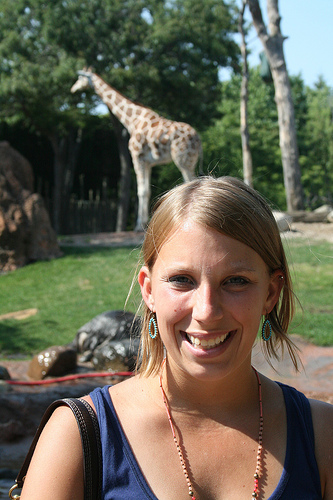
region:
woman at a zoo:
[9, 169, 332, 498]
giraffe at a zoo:
[57, 59, 241, 190]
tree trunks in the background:
[235, 6, 303, 213]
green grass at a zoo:
[24, 268, 134, 304]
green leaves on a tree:
[6, 2, 218, 59]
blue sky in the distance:
[292, 1, 331, 68]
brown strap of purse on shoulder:
[7, 392, 104, 499]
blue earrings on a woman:
[144, 310, 161, 340]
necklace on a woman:
[162, 418, 276, 499]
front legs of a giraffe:
[125, 156, 157, 238]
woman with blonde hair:
[121, 173, 315, 404]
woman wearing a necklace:
[107, 155, 305, 497]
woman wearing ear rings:
[109, 171, 312, 406]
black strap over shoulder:
[5, 384, 122, 499]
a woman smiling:
[124, 197, 312, 394]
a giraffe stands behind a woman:
[57, 52, 217, 250]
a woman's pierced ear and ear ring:
[256, 259, 303, 359]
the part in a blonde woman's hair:
[127, 169, 299, 263]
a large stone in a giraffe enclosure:
[0, 129, 90, 283]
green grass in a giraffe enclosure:
[20, 265, 123, 313]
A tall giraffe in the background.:
[65, 60, 213, 220]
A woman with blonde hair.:
[109, 165, 307, 407]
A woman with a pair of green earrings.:
[131, 166, 317, 377]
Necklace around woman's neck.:
[119, 197, 285, 496]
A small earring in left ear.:
[275, 266, 291, 291]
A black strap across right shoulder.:
[13, 386, 110, 498]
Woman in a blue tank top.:
[83, 164, 328, 498]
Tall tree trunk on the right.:
[264, 59, 308, 213]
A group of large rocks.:
[32, 310, 139, 376]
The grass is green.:
[1, 224, 142, 317]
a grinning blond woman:
[19, 173, 331, 499]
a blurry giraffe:
[68, 67, 203, 232]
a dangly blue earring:
[145, 306, 159, 338]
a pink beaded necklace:
[155, 354, 265, 499]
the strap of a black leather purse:
[8, 396, 101, 499]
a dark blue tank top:
[89, 381, 321, 499]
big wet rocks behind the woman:
[29, 309, 141, 383]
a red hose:
[2, 369, 137, 385]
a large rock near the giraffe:
[0, 141, 63, 271]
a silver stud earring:
[279, 273, 285, 280]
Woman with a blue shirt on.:
[26, 172, 327, 497]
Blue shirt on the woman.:
[80, 374, 324, 494]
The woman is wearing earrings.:
[136, 296, 287, 352]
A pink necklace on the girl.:
[129, 360, 279, 496]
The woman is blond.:
[115, 171, 314, 374]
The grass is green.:
[9, 219, 331, 353]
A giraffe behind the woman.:
[67, 58, 234, 252]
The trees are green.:
[0, 10, 326, 216]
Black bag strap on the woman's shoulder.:
[0, 388, 115, 496]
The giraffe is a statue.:
[55, 61, 255, 252]